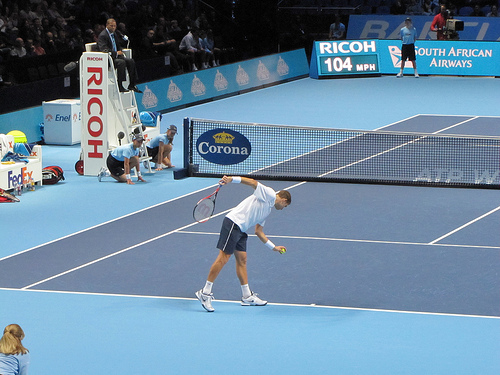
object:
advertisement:
[319, 41, 376, 54]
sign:
[195, 128, 252, 166]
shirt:
[224, 181, 279, 232]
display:
[319, 56, 378, 74]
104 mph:
[324, 56, 376, 72]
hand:
[218, 175, 231, 185]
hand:
[127, 179, 135, 185]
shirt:
[104, 28, 117, 53]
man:
[431, 5, 460, 41]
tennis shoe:
[240, 292, 267, 307]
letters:
[198, 141, 248, 155]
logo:
[86, 57, 104, 160]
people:
[97, 125, 177, 185]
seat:
[107, 123, 158, 149]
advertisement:
[195, 128, 251, 166]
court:
[0, 74, 498, 374]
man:
[96, 18, 142, 94]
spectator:
[178, 27, 203, 70]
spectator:
[154, 20, 169, 41]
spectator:
[204, 30, 223, 67]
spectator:
[148, 16, 171, 44]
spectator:
[117, 19, 132, 31]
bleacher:
[167, 80, 183, 103]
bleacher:
[141, 84, 158, 109]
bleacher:
[190, 74, 204, 98]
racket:
[193, 174, 229, 223]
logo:
[195, 128, 251, 167]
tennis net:
[178, 111, 499, 192]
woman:
[1, 322, 31, 375]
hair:
[0, 323, 30, 357]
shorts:
[215, 217, 248, 255]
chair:
[79, 51, 160, 177]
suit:
[97, 29, 138, 85]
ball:
[280, 248, 286, 254]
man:
[195, 174, 292, 311]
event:
[79, 94, 484, 319]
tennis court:
[0, 74, 499, 374]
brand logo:
[195, 128, 252, 166]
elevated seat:
[79, 43, 161, 176]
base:
[79, 52, 159, 176]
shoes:
[194, 289, 215, 312]